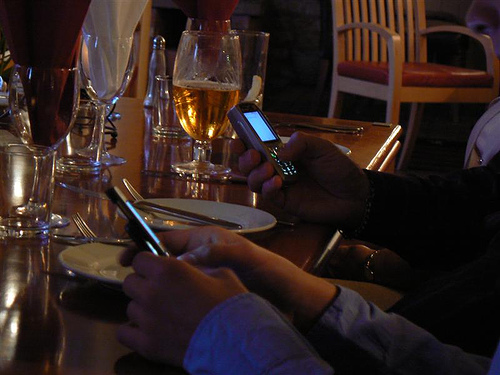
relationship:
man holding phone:
[275, 141, 399, 275] [227, 87, 318, 205]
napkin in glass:
[1, 9, 139, 75] [15, 39, 140, 175]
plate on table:
[137, 191, 295, 245] [104, 131, 330, 258]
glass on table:
[15, 39, 140, 175] [104, 131, 330, 258]